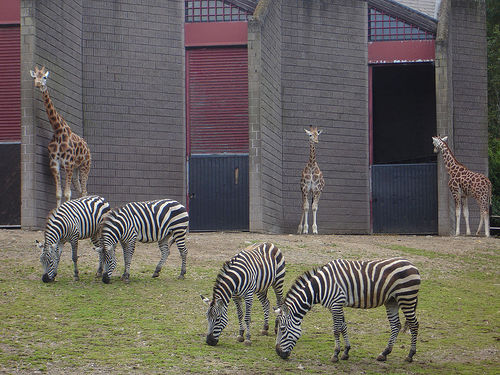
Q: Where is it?
A: This is at the field.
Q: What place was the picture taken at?
A: It was taken at the field.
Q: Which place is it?
A: It is a field.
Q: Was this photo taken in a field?
A: Yes, it was taken in a field.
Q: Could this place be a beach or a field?
A: It is a field.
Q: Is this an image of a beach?
A: No, the picture is showing a field.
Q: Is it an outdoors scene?
A: Yes, it is outdoors.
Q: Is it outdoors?
A: Yes, it is outdoors.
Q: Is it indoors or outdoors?
A: It is outdoors.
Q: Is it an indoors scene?
A: No, it is outdoors.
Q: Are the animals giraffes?
A: No, there are both giraffes and zebras.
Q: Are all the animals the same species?
A: No, there are both giraffes and zebras.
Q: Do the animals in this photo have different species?
A: Yes, they are giraffes and zebras.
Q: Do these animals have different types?
A: Yes, they are giraffes and zebras.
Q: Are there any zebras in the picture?
A: Yes, there is a zebra.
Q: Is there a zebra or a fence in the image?
A: Yes, there is a zebra.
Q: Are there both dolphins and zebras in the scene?
A: No, there is a zebra but no dolphins.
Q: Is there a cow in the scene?
A: No, there are no cows.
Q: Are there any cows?
A: No, there are no cows.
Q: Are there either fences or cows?
A: No, there are no cows or fences.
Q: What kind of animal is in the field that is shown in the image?
A: The animal is a zebra.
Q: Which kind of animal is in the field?
A: The animal is a zebra.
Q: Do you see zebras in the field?
A: Yes, there is a zebra in the field.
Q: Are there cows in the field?
A: No, there is a zebra in the field.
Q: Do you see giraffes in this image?
A: Yes, there is a giraffe.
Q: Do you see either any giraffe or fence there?
A: Yes, there is a giraffe.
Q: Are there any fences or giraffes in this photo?
A: Yes, there is a giraffe.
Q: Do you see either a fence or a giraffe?
A: Yes, there is a giraffe.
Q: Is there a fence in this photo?
A: No, there are no fences.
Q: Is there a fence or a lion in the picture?
A: No, there are no fences or lions.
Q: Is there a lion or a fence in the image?
A: No, there are no fences or lions.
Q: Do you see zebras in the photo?
A: Yes, there is a zebra.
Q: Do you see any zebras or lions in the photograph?
A: Yes, there is a zebra.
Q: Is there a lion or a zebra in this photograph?
A: Yes, there is a zebra.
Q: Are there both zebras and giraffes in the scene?
A: Yes, there are both a zebra and a giraffe.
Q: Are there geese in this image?
A: No, there are no geese.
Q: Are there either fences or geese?
A: No, there are no geese or fences.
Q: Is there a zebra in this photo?
A: Yes, there is a zebra.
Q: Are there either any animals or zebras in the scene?
A: Yes, there is a zebra.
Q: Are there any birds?
A: No, there are no birds.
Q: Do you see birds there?
A: No, there are no birds.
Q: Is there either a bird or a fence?
A: No, there are no birds or fences.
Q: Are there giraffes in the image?
A: Yes, there is a giraffe.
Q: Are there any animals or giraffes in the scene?
A: Yes, there is a giraffe.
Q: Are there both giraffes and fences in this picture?
A: No, there is a giraffe but no fences.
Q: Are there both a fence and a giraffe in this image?
A: No, there is a giraffe but no fences.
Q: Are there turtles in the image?
A: No, there are no turtles.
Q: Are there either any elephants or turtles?
A: No, there are no turtles or elephants.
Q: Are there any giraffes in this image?
A: Yes, there is a giraffe.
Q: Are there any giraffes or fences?
A: Yes, there is a giraffe.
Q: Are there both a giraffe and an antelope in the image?
A: No, there is a giraffe but no antelopes.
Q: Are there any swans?
A: No, there are no swans.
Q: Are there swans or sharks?
A: No, there are no swans or sharks.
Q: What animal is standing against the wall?
A: The giraffe is standing against the wall.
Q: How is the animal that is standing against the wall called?
A: The animal is a giraffe.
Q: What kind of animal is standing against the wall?
A: The animal is a giraffe.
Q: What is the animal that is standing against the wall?
A: The animal is a giraffe.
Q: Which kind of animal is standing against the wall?
A: The animal is a giraffe.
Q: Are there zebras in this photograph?
A: Yes, there is a zebra.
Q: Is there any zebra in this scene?
A: Yes, there is a zebra.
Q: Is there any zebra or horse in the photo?
A: Yes, there is a zebra.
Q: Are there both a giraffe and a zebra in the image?
A: Yes, there are both a zebra and a giraffe.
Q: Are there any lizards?
A: No, there are no lizards.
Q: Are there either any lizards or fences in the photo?
A: No, there are no lizards or fences.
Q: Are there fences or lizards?
A: No, there are no lizards or fences.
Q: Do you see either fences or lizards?
A: No, there are no lizards or fences.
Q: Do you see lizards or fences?
A: No, there are no lizards or fences.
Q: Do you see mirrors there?
A: No, there are no mirrors.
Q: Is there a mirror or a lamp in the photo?
A: No, there are no mirrors or lamps.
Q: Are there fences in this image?
A: No, there are no fences.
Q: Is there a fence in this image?
A: No, there are no fences.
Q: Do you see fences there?
A: No, there are no fences.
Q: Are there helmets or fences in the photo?
A: No, there are no fences or helmets.